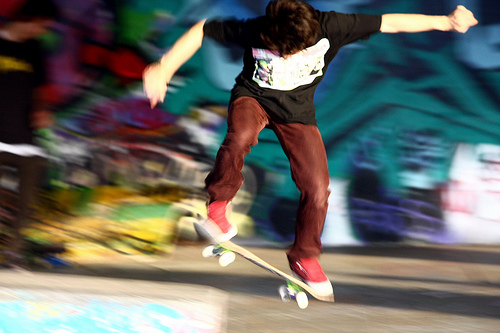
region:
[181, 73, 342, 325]
a guy in a skateboard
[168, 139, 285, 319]
a guy in a skateboard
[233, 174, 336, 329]
a guy in a skateboard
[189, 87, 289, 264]
a guy in a skateboard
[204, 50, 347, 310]
man wearing brown pants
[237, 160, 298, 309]
man wearing brown pants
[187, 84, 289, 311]
man wearing brown pants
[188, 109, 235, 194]
man wearing brown pants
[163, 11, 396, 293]
boy skating outside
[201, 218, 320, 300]
board under kid's feet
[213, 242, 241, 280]
wheel on the board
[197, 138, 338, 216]
pants on the kid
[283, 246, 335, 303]
red and white shoe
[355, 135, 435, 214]
blurry background of photo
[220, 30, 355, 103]
shirt with stuff on it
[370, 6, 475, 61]
arm of the kid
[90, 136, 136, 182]
painting on the wall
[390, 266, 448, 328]
ground below the kid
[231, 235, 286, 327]
a skateboard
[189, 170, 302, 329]
a skateboard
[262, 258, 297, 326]
a skateboard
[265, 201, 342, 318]
a skateboard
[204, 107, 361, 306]
a skateboard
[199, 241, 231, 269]
two hard white skateboard wheels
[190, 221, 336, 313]
skateboard slanted diagonally in motion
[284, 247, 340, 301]
red and white converse sneakers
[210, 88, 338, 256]
pair of red skinny jeans being worn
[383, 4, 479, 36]
horizontally outstretched human arm with clenched fist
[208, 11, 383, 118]
black t-shirt with white square graphic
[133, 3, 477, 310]
human boy on skateboard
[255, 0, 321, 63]
boy's head facing down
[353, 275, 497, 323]
shadows on blurry pavement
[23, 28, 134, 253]
blurred graffiti on cement wall